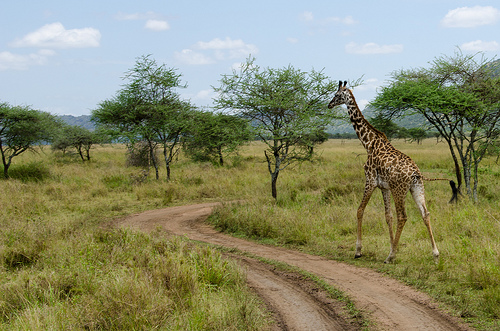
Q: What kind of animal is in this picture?
A: Giraffe.